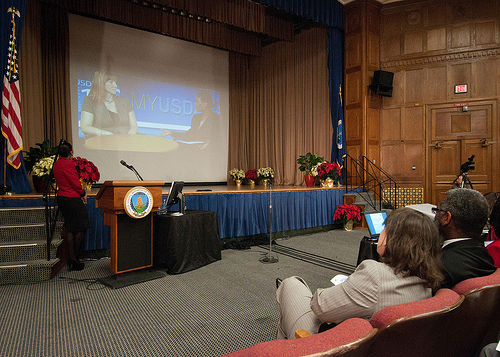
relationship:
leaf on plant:
[294, 152, 311, 166] [292, 150, 323, 174]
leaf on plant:
[300, 158, 315, 168] [298, 144, 325, 180]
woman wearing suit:
[269, 207, 448, 341] [269, 257, 433, 341]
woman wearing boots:
[34, 129, 112, 280] [52, 240, 91, 272]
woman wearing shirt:
[52, 141, 92, 273] [49, 153, 89, 201]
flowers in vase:
[72, 156, 102, 183] [79, 174, 93, 199]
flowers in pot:
[227, 166, 250, 179] [232, 174, 245, 191]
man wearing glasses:
[426, 187, 498, 299] [428, 200, 453, 216]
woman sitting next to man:
[269, 207, 449, 332] [426, 187, 498, 299]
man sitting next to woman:
[426, 187, 498, 299] [269, 207, 449, 332]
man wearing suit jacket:
[415, 177, 498, 311] [431, 238, 498, 283]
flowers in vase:
[328, 200, 368, 226] [339, 216, 362, 234]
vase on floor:
[339, 216, 362, 234] [4, 221, 412, 351]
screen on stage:
[64, 19, 239, 185] [6, 153, 396, 286]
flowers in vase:
[329, 199, 364, 227] [343, 218, 357, 230]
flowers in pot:
[310, 158, 340, 179] [317, 169, 337, 191]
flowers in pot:
[298, 147, 327, 174] [305, 170, 326, 186]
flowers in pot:
[253, 160, 278, 181] [262, 178, 275, 190]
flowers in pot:
[239, 167, 258, 182] [245, 175, 258, 187]